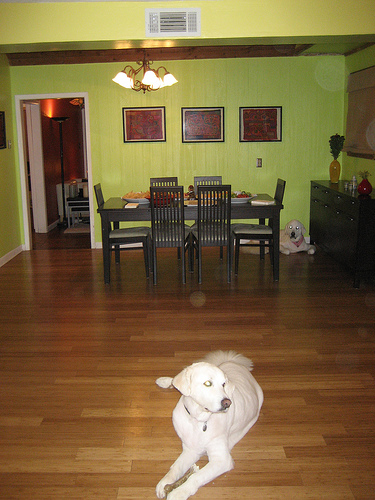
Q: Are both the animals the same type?
A: Yes, all the animals are dogs.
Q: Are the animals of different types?
A: No, all the animals are dogs.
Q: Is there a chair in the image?
A: Yes, there is a chair.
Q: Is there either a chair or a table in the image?
A: Yes, there is a chair.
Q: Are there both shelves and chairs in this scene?
A: No, there is a chair but no shelves.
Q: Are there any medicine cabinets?
A: No, there are no medicine cabinets.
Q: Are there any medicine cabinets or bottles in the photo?
A: No, there are no medicine cabinets or bottles.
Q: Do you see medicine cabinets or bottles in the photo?
A: No, there are no medicine cabinets or bottles.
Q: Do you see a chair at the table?
A: Yes, there is a chair at the table.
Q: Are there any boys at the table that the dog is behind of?
A: No, there is a chair at the table.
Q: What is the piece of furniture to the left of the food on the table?
A: The piece of furniture is a chair.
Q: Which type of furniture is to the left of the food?
A: The piece of furniture is a chair.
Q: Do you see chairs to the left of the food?
A: Yes, there is a chair to the left of the food.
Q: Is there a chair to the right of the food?
A: No, the chair is to the left of the food.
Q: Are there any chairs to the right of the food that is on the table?
A: No, the chair is to the left of the food.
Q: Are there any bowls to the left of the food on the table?
A: No, there is a chair to the left of the food.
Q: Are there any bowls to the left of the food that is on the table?
A: No, there is a chair to the left of the food.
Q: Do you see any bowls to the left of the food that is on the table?
A: No, there is a chair to the left of the food.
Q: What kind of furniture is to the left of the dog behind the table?
A: The piece of furniture is a chair.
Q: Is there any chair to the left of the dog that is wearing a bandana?
A: Yes, there is a chair to the left of the dog.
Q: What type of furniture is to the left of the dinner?
A: The piece of furniture is a chair.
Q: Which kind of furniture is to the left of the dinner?
A: The piece of furniture is a chair.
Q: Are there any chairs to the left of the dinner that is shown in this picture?
A: Yes, there is a chair to the left of the dinner.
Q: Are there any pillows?
A: No, there are no pillows.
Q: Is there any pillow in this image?
A: No, there are no pillows.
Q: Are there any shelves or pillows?
A: No, there are no pillows or shelves.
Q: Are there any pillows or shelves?
A: No, there are no pillows or shelves.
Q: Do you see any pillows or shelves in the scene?
A: No, there are no pillows or shelves.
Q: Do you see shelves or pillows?
A: No, there are no pillows or shelves.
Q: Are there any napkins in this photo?
A: No, there are no napkins.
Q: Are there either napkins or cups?
A: No, there are no napkins or cups.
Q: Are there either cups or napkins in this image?
A: No, there are no napkins or cups.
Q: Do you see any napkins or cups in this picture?
A: No, there are no napkins or cups.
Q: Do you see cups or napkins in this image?
A: No, there are no napkins or cups.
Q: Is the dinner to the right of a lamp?
A: Yes, the dinner is to the right of a lamp.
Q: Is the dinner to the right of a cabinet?
A: No, the dinner is to the right of a lamp.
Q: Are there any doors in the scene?
A: Yes, there is a door.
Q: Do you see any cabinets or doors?
A: Yes, there is a door.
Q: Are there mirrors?
A: No, there are no mirrors.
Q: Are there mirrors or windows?
A: No, there are no mirrors or windows.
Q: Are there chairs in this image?
A: Yes, there is a chair.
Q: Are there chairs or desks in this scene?
A: Yes, there is a chair.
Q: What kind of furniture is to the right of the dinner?
A: The piece of furniture is a chair.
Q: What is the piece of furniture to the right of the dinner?
A: The piece of furniture is a chair.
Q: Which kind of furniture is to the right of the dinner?
A: The piece of furniture is a chair.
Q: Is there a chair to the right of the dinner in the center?
A: Yes, there is a chair to the right of the dinner.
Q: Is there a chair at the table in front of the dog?
A: Yes, there is a chair at the table.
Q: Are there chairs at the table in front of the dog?
A: Yes, there is a chair at the table.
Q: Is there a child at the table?
A: No, there is a chair at the table.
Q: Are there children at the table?
A: No, there is a chair at the table.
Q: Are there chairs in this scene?
A: Yes, there is a chair.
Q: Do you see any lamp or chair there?
A: Yes, there is a chair.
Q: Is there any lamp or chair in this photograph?
A: Yes, there is a chair.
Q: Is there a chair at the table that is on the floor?
A: Yes, there is a chair at the table.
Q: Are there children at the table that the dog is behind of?
A: No, there is a chair at the table.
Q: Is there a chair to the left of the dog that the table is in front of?
A: Yes, there is a chair to the left of the dog.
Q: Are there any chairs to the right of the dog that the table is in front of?
A: No, the chair is to the left of the dog.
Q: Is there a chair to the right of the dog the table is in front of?
A: No, the chair is to the left of the dog.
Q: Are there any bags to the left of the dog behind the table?
A: No, there is a chair to the left of the dog.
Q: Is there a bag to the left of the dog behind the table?
A: No, there is a chair to the left of the dog.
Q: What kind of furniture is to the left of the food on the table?
A: The piece of furniture is a chair.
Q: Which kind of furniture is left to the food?
A: The piece of furniture is a chair.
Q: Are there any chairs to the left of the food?
A: Yes, there is a chair to the left of the food.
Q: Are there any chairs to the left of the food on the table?
A: Yes, there is a chair to the left of the food.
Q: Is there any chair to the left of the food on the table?
A: Yes, there is a chair to the left of the food.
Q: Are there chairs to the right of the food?
A: No, the chair is to the left of the food.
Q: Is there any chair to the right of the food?
A: No, the chair is to the left of the food.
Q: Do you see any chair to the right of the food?
A: No, the chair is to the left of the food.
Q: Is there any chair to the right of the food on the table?
A: No, the chair is to the left of the food.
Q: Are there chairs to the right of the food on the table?
A: No, the chair is to the left of the food.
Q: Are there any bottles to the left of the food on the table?
A: No, there is a chair to the left of the food.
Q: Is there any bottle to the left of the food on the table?
A: No, there is a chair to the left of the food.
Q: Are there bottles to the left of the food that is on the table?
A: No, there is a chair to the left of the food.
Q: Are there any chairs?
A: Yes, there is a chair.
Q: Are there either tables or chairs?
A: Yes, there is a chair.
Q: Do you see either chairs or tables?
A: Yes, there is a chair.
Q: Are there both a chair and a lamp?
A: Yes, there are both a chair and a lamp.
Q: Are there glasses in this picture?
A: No, there are no glasses.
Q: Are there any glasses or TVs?
A: No, there are no glasses or tvs.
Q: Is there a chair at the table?
A: Yes, there is a chair at the table.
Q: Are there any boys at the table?
A: No, there is a chair at the table.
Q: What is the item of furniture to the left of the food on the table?
A: The piece of furniture is a chair.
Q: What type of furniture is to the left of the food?
A: The piece of furniture is a chair.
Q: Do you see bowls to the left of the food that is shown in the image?
A: No, there is a chair to the left of the food.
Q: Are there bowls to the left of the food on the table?
A: No, there is a chair to the left of the food.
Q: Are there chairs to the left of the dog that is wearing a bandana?
A: Yes, there is a chair to the left of the dog.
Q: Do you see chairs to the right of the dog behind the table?
A: No, the chair is to the left of the dog.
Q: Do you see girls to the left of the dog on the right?
A: No, there is a chair to the left of the dog.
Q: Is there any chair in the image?
A: Yes, there is a chair.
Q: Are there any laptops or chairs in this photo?
A: Yes, there is a chair.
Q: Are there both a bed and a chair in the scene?
A: No, there is a chair but no beds.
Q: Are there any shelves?
A: No, there are no shelves.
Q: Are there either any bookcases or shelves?
A: No, there are no shelves or bookcases.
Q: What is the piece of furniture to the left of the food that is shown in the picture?
A: The piece of furniture is a chair.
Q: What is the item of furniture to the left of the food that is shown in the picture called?
A: The piece of furniture is a chair.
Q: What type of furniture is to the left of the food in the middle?
A: The piece of furniture is a chair.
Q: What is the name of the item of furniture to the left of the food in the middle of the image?
A: The piece of furniture is a chair.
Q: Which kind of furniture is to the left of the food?
A: The piece of furniture is a chair.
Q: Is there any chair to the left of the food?
A: Yes, there is a chair to the left of the food.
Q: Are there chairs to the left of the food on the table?
A: Yes, there is a chair to the left of the food.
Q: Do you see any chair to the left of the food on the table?
A: Yes, there is a chair to the left of the food.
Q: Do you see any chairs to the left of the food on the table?
A: Yes, there is a chair to the left of the food.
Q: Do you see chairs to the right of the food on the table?
A: No, the chair is to the left of the food.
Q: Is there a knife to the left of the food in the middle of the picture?
A: No, there is a chair to the left of the food.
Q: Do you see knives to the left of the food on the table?
A: No, there is a chair to the left of the food.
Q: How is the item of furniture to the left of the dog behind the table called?
A: The piece of furniture is a chair.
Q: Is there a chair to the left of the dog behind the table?
A: Yes, there is a chair to the left of the dog.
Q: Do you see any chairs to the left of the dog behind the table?
A: Yes, there is a chair to the left of the dog.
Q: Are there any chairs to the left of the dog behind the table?
A: Yes, there is a chair to the left of the dog.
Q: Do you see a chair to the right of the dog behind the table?
A: No, the chair is to the left of the dog.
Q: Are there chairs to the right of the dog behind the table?
A: No, the chair is to the left of the dog.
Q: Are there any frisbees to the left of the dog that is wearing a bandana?
A: No, there is a chair to the left of the dog.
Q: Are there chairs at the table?
A: Yes, there is a chair at the table.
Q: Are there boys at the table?
A: No, there is a chair at the table.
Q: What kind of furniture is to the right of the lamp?
A: The piece of furniture is a chair.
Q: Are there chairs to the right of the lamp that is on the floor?
A: Yes, there is a chair to the right of the lamp.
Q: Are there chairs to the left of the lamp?
A: No, the chair is to the right of the lamp.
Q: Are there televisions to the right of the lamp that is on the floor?
A: No, there is a chair to the right of the lamp.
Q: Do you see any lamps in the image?
A: Yes, there is a lamp.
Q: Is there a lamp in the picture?
A: Yes, there is a lamp.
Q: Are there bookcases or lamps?
A: Yes, there is a lamp.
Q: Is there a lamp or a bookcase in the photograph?
A: Yes, there is a lamp.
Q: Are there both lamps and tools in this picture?
A: No, there is a lamp but no tools.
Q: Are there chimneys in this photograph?
A: No, there are no chimneys.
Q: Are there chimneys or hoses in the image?
A: No, there are no chimneys or hoses.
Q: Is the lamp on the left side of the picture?
A: Yes, the lamp is on the left of the image.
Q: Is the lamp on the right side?
A: No, the lamp is on the left of the image.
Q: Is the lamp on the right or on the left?
A: The lamp is on the left of the image.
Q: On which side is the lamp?
A: The lamp is on the left of the image.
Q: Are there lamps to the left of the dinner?
A: Yes, there is a lamp to the left of the dinner.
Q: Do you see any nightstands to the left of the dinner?
A: No, there is a lamp to the left of the dinner.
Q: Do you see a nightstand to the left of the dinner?
A: No, there is a lamp to the left of the dinner.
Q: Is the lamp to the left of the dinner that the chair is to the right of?
A: Yes, the lamp is to the left of the dinner.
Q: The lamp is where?
A: The lamp is on the floor.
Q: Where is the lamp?
A: The lamp is on the floor.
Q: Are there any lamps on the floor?
A: Yes, there is a lamp on the floor.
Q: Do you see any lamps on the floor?
A: Yes, there is a lamp on the floor.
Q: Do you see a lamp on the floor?
A: Yes, there is a lamp on the floor.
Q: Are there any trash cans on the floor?
A: No, there is a lamp on the floor.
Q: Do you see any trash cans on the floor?
A: No, there is a lamp on the floor.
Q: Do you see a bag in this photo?
A: No, there are no bags.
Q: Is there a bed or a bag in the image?
A: No, there are no bags or beds.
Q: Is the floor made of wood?
A: Yes, the floor is made of wood.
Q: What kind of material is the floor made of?
A: The floor is made of wood.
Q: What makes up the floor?
A: The floor is made of wood.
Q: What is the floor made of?
A: The floor is made of wood.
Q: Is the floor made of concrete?
A: No, the floor is made of wood.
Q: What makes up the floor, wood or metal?
A: The floor is made of wood.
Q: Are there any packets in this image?
A: No, there are no packets.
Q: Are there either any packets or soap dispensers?
A: No, there are no packets or soap dispensers.